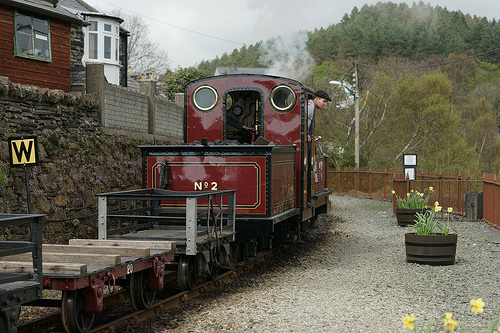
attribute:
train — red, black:
[137, 73, 329, 241]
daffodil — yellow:
[407, 200, 454, 235]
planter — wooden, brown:
[405, 233, 457, 265]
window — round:
[193, 85, 219, 111]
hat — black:
[314, 89, 331, 100]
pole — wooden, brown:
[354, 61, 360, 171]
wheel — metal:
[60, 290, 102, 333]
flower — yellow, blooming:
[402, 297, 485, 332]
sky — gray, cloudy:
[83, 0, 499, 73]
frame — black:
[402, 152, 419, 167]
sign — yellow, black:
[9, 136, 40, 167]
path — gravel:
[153, 194, 499, 332]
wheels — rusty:
[127, 253, 202, 308]